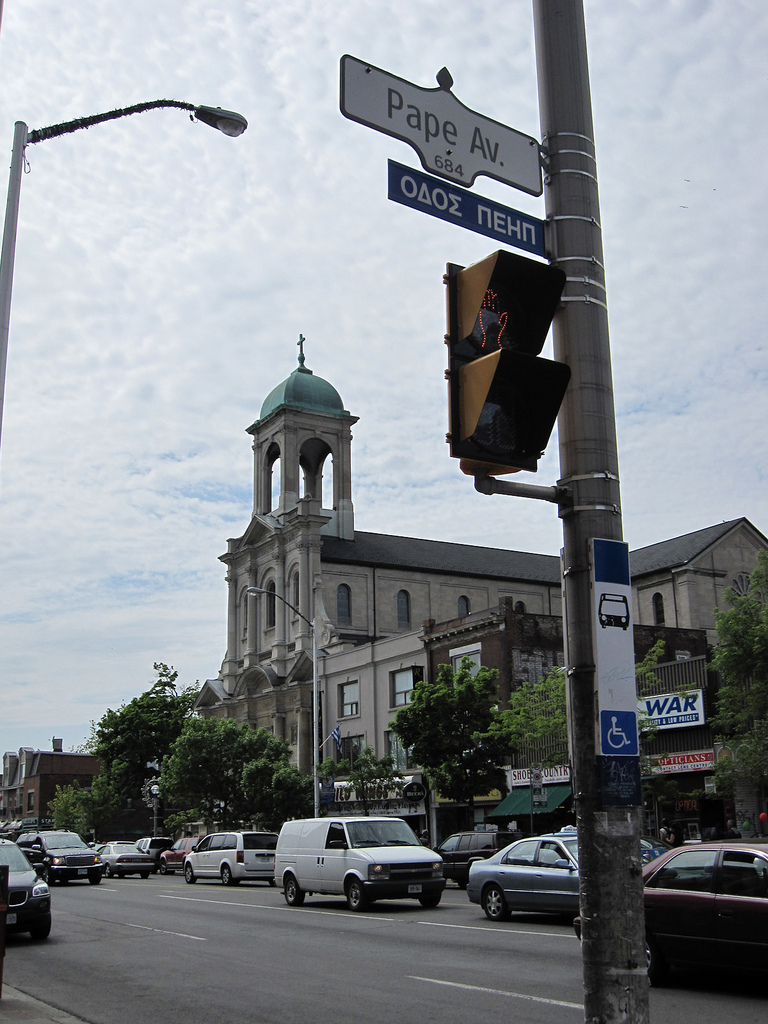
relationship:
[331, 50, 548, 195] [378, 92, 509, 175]
sign reads pape av.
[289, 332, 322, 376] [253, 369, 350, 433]
cross on top of dome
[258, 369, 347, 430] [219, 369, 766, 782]
dome on a building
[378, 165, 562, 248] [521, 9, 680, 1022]
sign on a pole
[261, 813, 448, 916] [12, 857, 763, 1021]
van driving on street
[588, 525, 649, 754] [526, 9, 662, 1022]
sign attached to pole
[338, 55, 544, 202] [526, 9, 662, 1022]
sign attached to pole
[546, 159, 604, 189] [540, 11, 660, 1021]
brackets around pole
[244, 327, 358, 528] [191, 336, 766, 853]
belfry on top of building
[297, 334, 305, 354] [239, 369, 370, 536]
cross on top of belfry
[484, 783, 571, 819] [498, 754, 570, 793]
awning below sign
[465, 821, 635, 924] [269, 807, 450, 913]
car in front of van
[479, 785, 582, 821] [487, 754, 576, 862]
awning on storefront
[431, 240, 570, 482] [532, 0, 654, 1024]
crosswalk sign on a pole